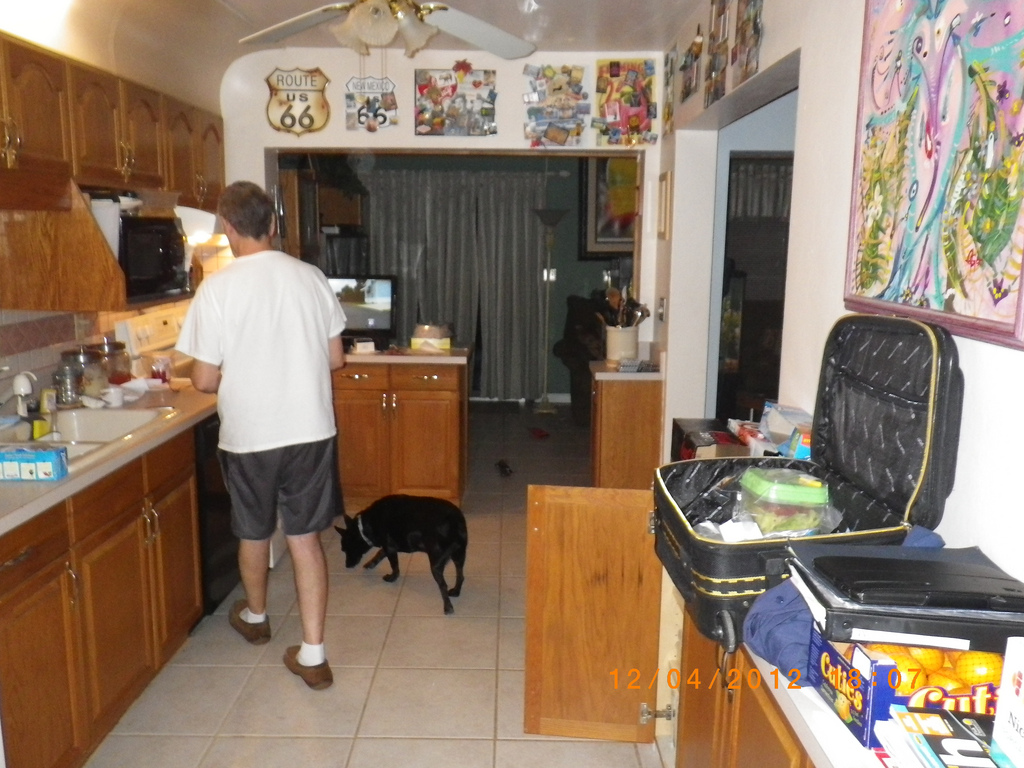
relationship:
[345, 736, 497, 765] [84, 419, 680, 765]
tile in floor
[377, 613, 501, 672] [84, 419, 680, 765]
tile in floor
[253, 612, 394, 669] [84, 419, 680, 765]
tile in floor